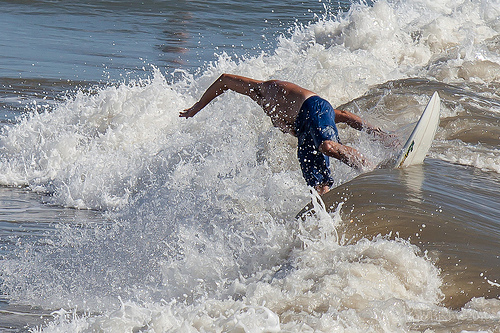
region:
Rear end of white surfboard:
[396, 88, 442, 170]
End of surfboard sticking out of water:
[394, 89, 441, 170]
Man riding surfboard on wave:
[178, 71, 401, 200]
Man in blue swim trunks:
[177, 72, 404, 199]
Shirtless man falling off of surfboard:
[180, 72, 405, 198]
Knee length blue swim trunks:
[295, 94, 341, 189]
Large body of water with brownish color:
[1, 0, 498, 330]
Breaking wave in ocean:
[3, 0, 498, 329]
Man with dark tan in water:
[178, 70, 399, 199]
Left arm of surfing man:
[178, 71, 263, 118]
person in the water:
[193, 55, 370, 188]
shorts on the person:
[285, 100, 347, 194]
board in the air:
[385, 92, 455, 173]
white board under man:
[379, 87, 450, 188]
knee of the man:
[306, 133, 356, 178]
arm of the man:
[168, 61, 252, 151]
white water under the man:
[133, 149, 250, 240]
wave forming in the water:
[266, 190, 417, 277]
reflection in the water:
[137, 4, 214, 72]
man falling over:
[211, 35, 399, 191]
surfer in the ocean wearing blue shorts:
[179, 73, 401, 200]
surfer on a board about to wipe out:
[178, 71, 402, 201]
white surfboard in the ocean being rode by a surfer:
[391, 90, 442, 171]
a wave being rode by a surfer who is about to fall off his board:
[1, 0, 496, 246]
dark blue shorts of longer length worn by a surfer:
[296, 93, 342, 187]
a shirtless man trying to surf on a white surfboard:
[180, 73, 402, 195]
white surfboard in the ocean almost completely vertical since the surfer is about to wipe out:
[389, 88, 441, 169]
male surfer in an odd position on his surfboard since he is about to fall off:
[179, 73, 401, 199]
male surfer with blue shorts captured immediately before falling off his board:
[181, 72, 401, 200]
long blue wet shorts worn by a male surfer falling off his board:
[296, 95, 341, 187]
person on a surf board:
[180, 55, 455, 180]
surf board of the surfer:
[390, 81, 455, 176]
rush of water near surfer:
[45, 95, 271, 300]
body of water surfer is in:
[15, 5, 150, 60]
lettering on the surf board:
[396, 130, 416, 170]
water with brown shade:
[375, 170, 470, 220]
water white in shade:
[90, 130, 142, 160]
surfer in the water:
[177, 53, 399, 205]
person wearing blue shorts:
[291, 89, 330, 186]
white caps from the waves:
[193, 275, 448, 331]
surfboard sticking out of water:
[398, 86, 469, 206]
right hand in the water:
[326, 106, 395, 145]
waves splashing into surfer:
[273, 0, 468, 98]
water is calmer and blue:
[16, 15, 198, 87]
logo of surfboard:
[389, 128, 421, 173]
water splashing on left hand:
[158, 97, 195, 139]